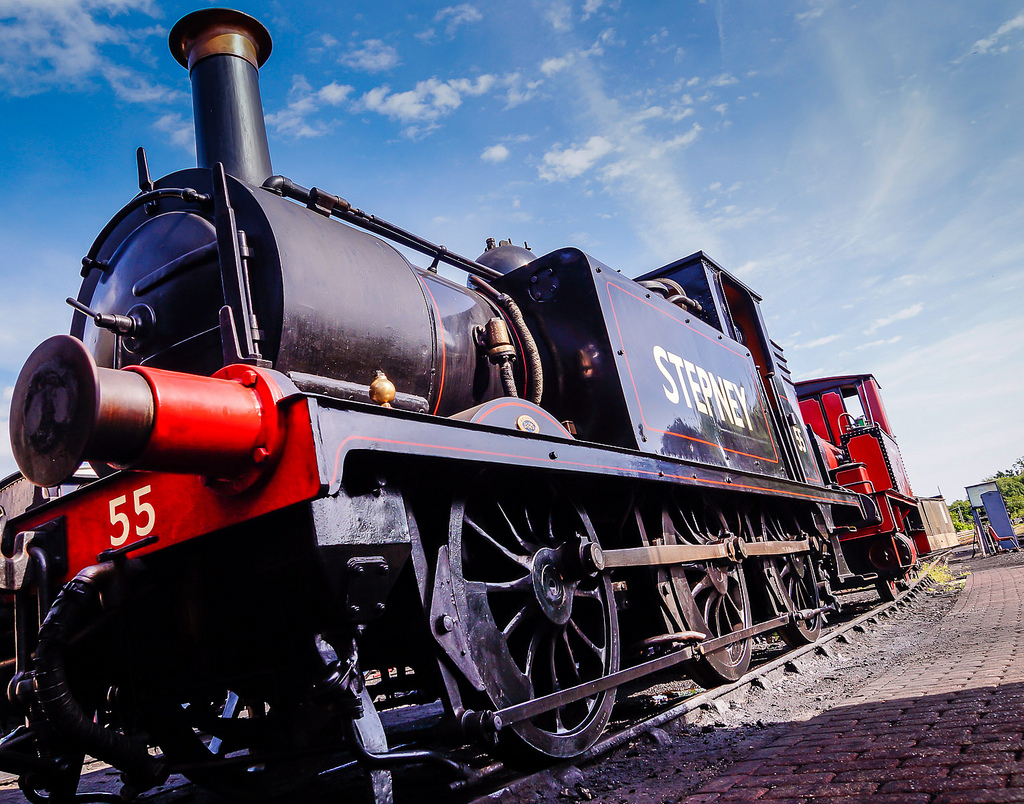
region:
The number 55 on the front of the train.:
[96, 487, 157, 542]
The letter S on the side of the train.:
[646, 341, 678, 414]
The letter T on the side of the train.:
[667, 347, 693, 408]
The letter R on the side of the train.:
[693, 361, 719, 428]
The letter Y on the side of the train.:
[731, 376, 751, 428]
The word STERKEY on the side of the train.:
[652, 338, 760, 431]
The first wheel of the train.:
[433, 470, 626, 759]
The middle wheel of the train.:
[631, 496, 759, 674]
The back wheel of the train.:
[734, 522, 842, 644]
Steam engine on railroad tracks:
[7, 7, 883, 798]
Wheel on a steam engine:
[447, 462, 618, 764]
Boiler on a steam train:
[68, 168, 560, 421]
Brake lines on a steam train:
[30, 552, 167, 778]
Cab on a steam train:
[630, 247, 776, 365]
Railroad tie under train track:
[750, 653, 792, 688]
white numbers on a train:
[87, 478, 177, 559]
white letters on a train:
[639, 328, 773, 452]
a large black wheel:
[387, 386, 625, 759]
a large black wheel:
[653, 500, 764, 704]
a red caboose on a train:
[784, 347, 934, 595]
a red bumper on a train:
[16, 333, 356, 615]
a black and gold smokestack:
[143, 9, 295, 200]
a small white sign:
[956, 467, 1007, 560]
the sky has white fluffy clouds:
[349, 63, 691, 194]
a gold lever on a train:
[475, 301, 539, 426]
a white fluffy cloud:
[672, 97, 691, 120]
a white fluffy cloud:
[639, 158, 712, 177]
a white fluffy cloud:
[536, 32, 622, 90]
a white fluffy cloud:
[30, 10, 104, 74]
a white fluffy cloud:
[77, 56, 131, 99]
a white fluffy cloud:
[154, 118, 199, 163]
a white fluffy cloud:
[296, 45, 366, 131]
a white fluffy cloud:
[823, 158, 937, 295]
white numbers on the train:
[105, 484, 164, 549]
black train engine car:
[23, 23, 848, 783]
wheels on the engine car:
[117, 459, 848, 745]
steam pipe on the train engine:
[165, 10, 289, 175]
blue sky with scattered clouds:
[15, 14, 1002, 473]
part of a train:
[424, 473, 646, 752]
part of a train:
[635, 508, 768, 687]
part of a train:
[10, 334, 287, 512]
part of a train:
[157, 4, 298, 185]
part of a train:
[63, 164, 551, 408]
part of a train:
[483, 244, 797, 483]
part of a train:
[572, 521, 829, 563]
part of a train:
[474, 601, 829, 732]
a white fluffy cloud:
[564, 89, 610, 153]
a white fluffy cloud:
[605, 104, 669, 162]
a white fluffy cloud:
[351, 1, 485, 173]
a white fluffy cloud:
[301, 4, 377, 138]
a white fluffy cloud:
[514, 25, 560, 80]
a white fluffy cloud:
[58, 25, 136, 127]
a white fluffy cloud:
[708, 139, 778, 261]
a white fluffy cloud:
[737, 230, 786, 308]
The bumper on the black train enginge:
[2, 335, 281, 509]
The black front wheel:
[428, 471, 624, 757]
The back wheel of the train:
[751, 511, 827, 644]